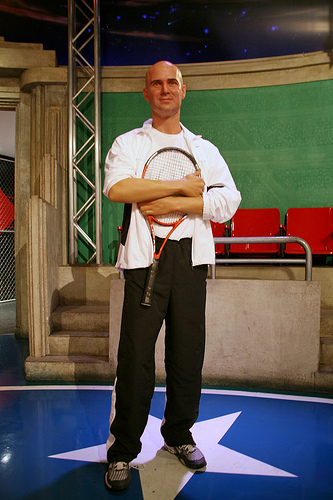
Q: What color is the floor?
A: Blue and white.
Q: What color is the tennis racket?
A: Red.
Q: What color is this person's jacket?
A: White.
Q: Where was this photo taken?
A: Inside a building.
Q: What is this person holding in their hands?
A: A tennis racket.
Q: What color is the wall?
A: Green.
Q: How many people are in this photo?
A: One.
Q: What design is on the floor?
A: A large white star.